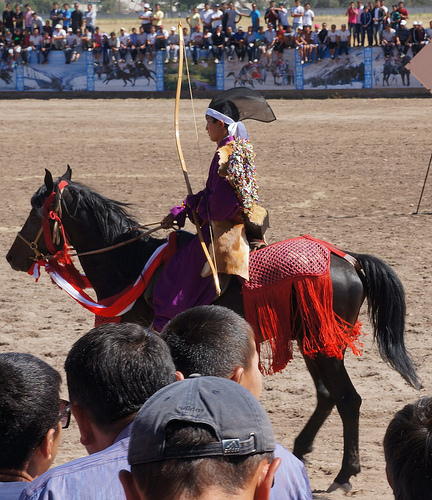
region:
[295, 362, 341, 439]
aprt of a leg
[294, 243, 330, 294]
part of a horse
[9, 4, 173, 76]
A group of people watching the show.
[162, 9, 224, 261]
A bow in a person's hand.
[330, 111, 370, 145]
Dirt on the ground.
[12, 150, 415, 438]
A black horse.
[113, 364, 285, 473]
A man's grey hat.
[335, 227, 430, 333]
A horse's black tail.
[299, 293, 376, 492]
A horse's black leg.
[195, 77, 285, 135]
A person's head dress.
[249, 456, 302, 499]
A man's ear.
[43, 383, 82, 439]
A person's sunglasses.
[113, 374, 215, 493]
This is a person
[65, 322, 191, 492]
This is a person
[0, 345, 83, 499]
This is a person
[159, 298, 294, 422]
This is a person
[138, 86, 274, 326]
This is a person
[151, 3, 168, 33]
This is a person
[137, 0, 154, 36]
This is a person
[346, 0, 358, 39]
This is a person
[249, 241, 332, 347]
red blanket on back of horse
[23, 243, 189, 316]
red and white reins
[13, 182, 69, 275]
harness around the face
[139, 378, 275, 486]
back of man's head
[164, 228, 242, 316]
purple garment on person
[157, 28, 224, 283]
man carring a bow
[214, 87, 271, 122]
black head peice on head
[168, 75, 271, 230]
this is a lady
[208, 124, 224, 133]
the lady is light skinned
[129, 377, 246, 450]
this is a cap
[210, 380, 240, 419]
the cap is black in color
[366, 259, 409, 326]
this is the tail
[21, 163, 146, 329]
this is a horse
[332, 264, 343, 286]
the horse is black in color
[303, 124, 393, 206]
this is the ground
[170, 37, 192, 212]
this is a stick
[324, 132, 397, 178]
this is the ground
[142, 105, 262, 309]
person riding the horse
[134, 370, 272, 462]
navy hat man is wearing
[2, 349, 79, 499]
person wearing glasses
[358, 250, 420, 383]
black tail of the horse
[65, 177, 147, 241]
black mane of the horse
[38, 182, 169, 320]
red and white ribbons on the horse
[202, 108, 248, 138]
white band tied around the person's head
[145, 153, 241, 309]
purple dress the person is wearing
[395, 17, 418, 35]
a cauliflower in the bowl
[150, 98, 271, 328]
boy on horse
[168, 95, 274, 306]
boy holding a bow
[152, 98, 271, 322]
boy wearing purple clothes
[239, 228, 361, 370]
red blanket on horse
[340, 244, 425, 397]
black tail on horse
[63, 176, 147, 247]
black mane on horse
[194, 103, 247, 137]
white headband on boy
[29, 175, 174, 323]
bright red harness on horse